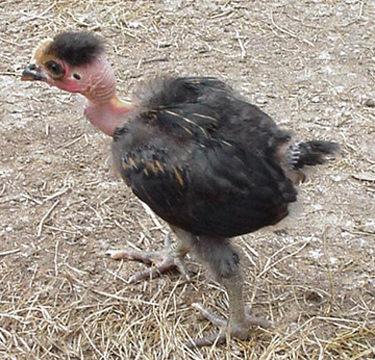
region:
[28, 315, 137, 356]
Gray straw on ground.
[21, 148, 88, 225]
Dried out dirt under straw.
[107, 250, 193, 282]
Bird claws walking on straw.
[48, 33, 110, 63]
Black turf of hair on bird's head.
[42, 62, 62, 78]
Round alert eye of bird.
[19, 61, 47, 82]
little baby bird's beck.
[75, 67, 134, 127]
Pink neck of little bird.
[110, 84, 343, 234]
Black feathers of little bird.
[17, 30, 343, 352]
Little bird with pink neck walking.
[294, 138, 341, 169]
Little black tail of bird.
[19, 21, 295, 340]
Baby bird is standing in ground.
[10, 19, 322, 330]
Ground is brown in color.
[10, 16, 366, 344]
Ground is dirty with hay.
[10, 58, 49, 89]
Beak is black color.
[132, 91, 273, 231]
Feathers are black color.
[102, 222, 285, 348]
Bird has two legs.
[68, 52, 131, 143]
Bird neck is pink color.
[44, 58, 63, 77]
Eyes are black color.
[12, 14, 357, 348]
Day time picture.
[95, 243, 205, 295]
Nails are sharp and pointed.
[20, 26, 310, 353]
Brown baby bird walking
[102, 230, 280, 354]
Brown bird feet on the ground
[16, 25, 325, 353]
Baby turkey trying to walk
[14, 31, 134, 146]
Head of a baby turkey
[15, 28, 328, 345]
Baby turkey walking on straw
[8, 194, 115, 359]
Dirt ground covered in hay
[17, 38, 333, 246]
Small bird with brown feathers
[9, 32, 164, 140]
Small bird with pink neck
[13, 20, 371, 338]
Young bird walking on hay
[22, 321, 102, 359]
Yellow straw on ground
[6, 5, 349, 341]
Baby turkey standing on dried hay.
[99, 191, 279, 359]
Large feet of a baby turkey.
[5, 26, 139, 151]
Neck and head of a baby turkey.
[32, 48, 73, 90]
Large eye of a baby turkey.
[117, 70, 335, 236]
Black fur of a turkey.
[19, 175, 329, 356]
Dried hay on the ground.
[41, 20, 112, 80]
Black fur on top of baby turkey's head.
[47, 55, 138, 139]
Pinkish neck of a baby turkey.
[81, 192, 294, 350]
Gray legs and feet of a baby turkey.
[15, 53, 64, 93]
Beak of a baby turkey.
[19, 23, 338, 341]
baby ostrich bird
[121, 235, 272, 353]
white feet of the ostrich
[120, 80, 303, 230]
black body of the bird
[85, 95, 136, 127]
pink neck of the ostrich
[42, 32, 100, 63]
black fuzzy feathers on the ostrich's head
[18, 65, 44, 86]
beak of the ostrich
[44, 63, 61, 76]
eye of the ostrich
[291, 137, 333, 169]
tail feathers of the ostrich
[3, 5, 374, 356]
straw littered on the ground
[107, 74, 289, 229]
feathers on the bird's body